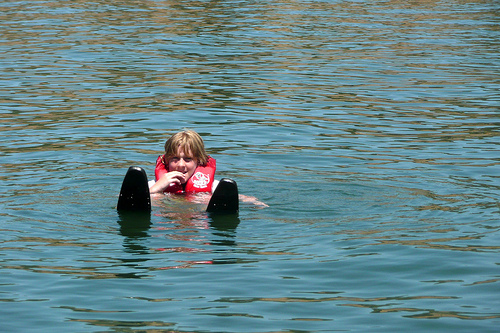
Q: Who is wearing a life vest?
A: The boy.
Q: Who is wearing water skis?
A: The boy.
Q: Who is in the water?
A: The boy.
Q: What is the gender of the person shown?
A: Male.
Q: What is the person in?
A: Water.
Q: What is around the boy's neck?
A: Life jacket.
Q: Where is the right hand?
A: Against the male's mouth.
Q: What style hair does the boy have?
A: Ragged.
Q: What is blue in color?
A: Water.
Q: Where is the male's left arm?
A: Under the water.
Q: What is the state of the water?
A: Calm.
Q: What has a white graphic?
A: Life jacket.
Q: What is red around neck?
A: Safety vest.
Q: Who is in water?
A: The boy.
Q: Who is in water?
A: The boy.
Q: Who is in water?
A: The boy.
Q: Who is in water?
A: The boy.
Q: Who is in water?
A: The boy.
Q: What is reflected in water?
A: The boy.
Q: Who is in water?
A: The boy.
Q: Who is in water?
A: The boy.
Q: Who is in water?
A: The boy.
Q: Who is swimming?
A: A young boy.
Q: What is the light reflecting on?
A: Water.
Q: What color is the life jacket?
A: Red.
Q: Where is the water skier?
A: In the water.